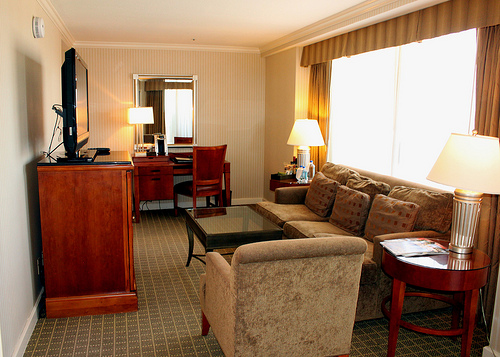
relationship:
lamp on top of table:
[286, 118, 328, 183] [267, 170, 323, 195]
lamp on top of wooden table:
[429, 118, 498, 263] [379, 228, 496, 350]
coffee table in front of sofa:
[182, 204, 284, 252] [259, 158, 453, 240]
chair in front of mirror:
[176, 142, 227, 212] [134, 66, 201, 144]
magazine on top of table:
[379, 231, 446, 262] [367, 226, 494, 356]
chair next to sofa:
[198, 230, 368, 355] [256, 161, 458, 320]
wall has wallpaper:
[69, 42, 266, 207] [233, 52, 256, 186]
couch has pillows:
[253, 159, 464, 324] [302, 157, 452, 242]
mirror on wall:
[131, 73, 197, 148] [69, 42, 266, 207]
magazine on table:
[379, 231, 446, 262] [328, 169, 490, 324]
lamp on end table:
[429, 118, 498, 263] [375, 235, 497, 355]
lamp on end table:
[286, 118, 328, 183] [375, 235, 497, 355]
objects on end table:
[253, 148, 314, 198] [266, 172, 313, 189]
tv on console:
[59, 48, 91, 159] [40, 147, 137, 316]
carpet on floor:
[25, 216, 490, 353] [30, 202, 489, 354]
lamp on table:
[429, 118, 498, 263] [376, 221, 462, 330]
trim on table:
[183, 208, 269, 270] [183, 205, 283, 267]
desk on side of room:
[131, 150, 237, 212] [2, 0, 497, 352]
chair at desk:
[187, 142, 224, 213] [133, 155, 233, 215]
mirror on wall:
[127, 69, 202, 151] [184, 62, 268, 167]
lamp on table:
[128, 101, 158, 151] [92, 144, 235, 210]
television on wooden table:
[43, 42, 109, 163] [387, 231, 484, 278]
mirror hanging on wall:
[131, 73, 197, 148] [59, 35, 268, 203]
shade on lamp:
[425, 140, 484, 197] [429, 118, 498, 263]